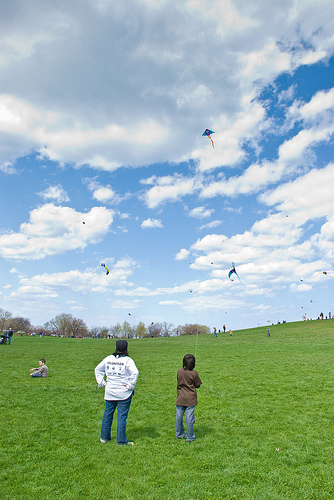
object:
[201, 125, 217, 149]
kite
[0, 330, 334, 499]
grass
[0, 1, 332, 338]
sky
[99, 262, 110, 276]
kite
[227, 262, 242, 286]
kite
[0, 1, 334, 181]
clouds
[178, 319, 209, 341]
trees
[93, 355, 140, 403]
shirt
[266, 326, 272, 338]
people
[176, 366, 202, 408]
brown shirt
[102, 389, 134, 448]
jeans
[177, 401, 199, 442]
jeans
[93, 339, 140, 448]
person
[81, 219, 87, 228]
kites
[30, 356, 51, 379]
boy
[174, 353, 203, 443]
boy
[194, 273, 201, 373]
string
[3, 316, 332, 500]
ground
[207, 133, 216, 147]
tail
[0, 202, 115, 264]
cloud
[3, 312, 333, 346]
hill